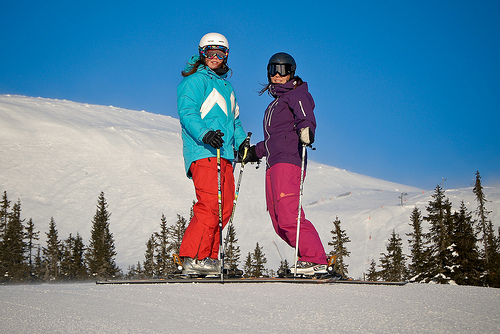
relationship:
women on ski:
[145, 25, 333, 305] [138, 239, 356, 316]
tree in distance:
[41, 204, 159, 279] [0, 178, 178, 275]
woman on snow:
[159, 22, 257, 290] [49, 112, 158, 198]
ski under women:
[138, 239, 356, 316] [145, 25, 333, 305]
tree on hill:
[41, 204, 159, 279] [80, 78, 157, 144]